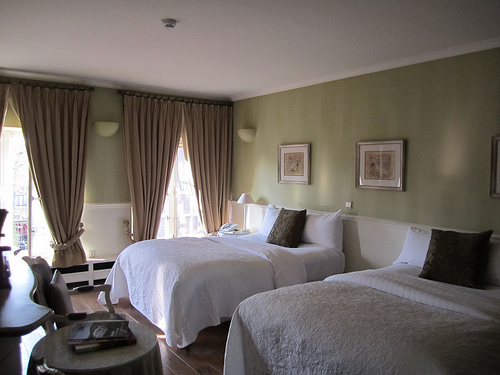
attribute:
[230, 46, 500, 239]
wall — green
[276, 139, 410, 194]
pictures — next to each other, framed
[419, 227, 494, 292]
pillow — brown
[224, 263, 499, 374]
bedspread — white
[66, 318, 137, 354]
books — stacked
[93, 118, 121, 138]
light — hanging, white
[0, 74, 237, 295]
wall — green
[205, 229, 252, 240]
table — round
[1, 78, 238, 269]
curtains — tan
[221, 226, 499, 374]
bed — white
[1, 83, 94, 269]
curtain — hanging, brown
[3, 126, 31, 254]
window — bright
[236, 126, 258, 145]
light — white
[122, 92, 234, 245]
curtains — brown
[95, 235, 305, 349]
bedspread — white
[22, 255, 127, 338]
chair — across from bed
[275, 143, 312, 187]
picture — framed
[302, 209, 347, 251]
pillow — white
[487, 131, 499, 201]
picture — framed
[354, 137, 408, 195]
frame — brown